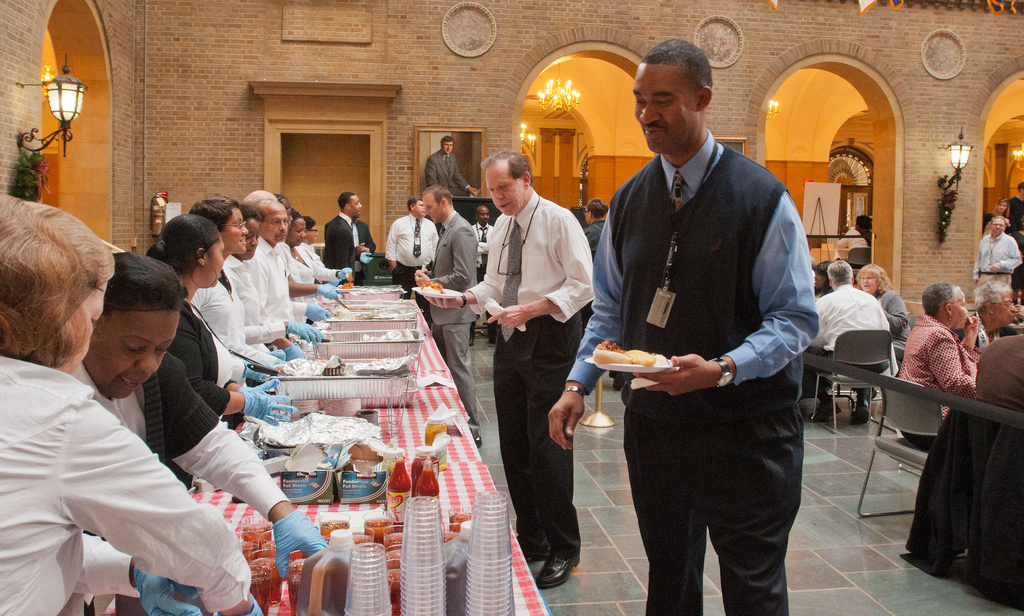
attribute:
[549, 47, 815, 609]
man — african american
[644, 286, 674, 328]
badge — name badge, card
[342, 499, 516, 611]
cups in stack — plastic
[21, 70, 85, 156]
light — fixture, attached, mounted, illuminated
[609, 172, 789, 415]
vest — blue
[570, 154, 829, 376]
shirt — blue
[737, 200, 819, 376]
sleeve — long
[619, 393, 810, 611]
pants — black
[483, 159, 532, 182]
hair — brown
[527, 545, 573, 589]
shoes — black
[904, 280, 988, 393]
woman — eating, sitting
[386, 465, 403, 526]
bottle — clear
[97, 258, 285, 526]
woman — reaching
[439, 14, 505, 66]
decoration — circular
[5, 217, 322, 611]
women — helping